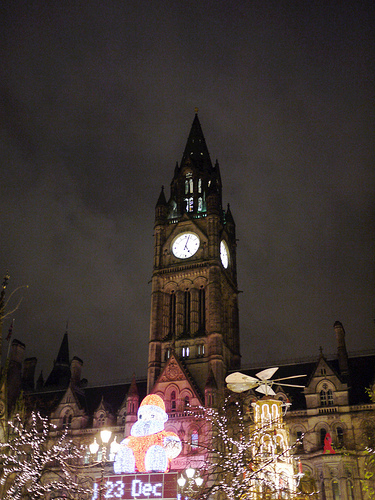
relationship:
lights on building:
[1, 374, 318, 494] [114, 97, 292, 403]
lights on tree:
[22, 413, 97, 497] [0, 410, 92, 497]